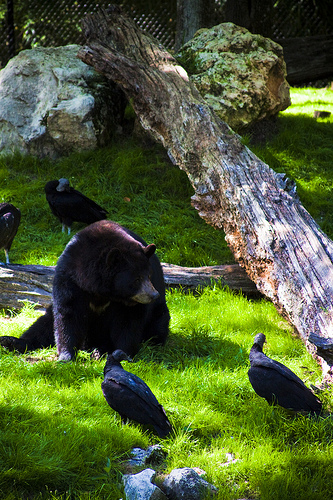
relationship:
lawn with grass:
[4, 369, 98, 462] [19, 386, 48, 416]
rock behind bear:
[172, 23, 291, 134] [0, 219, 173, 363]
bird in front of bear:
[100, 349, 177, 443] [52, 219, 172, 364]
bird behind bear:
[41, 178, 110, 236] [50, 208, 185, 344]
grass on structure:
[0, 84, 332, 497] [0, 261, 54, 315]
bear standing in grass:
[52, 219, 172, 364] [6, 297, 325, 492]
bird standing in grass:
[100, 349, 177, 443] [6, 297, 325, 492]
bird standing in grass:
[247, 333, 323, 420] [6, 297, 325, 492]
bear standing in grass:
[0, 219, 173, 363] [0, 84, 332, 497]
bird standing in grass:
[41, 178, 110, 236] [0, 84, 332, 497]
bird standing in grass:
[100, 349, 177, 443] [0, 84, 332, 497]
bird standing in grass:
[247, 333, 323, 420] [0, 84, 332, 497]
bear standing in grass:
[52, 219, 172, 364] [0, 84, 332, 497]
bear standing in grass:
[0, 219, 173, 363] [176, 290, 273, 327]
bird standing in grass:
[100, 349, 177, 443] [176, 290, 273, 327]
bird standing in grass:
[247, 333, 323, 420] [176, 290, 273, 327]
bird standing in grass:
[247, 333, 325, 412] [0, 84, 332, 497]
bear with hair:
[52, 219, 172, 364] [52, 219, 170, 366]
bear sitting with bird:
[52, 219, 172, 364] [247, 333, 329, 423]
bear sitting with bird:
[52, 219, 172, 364] [97, 347, 175, 442]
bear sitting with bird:
[52, 219, 172, 364] [41, 172, 109, 233]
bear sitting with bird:
[52, 219, 172, 364] [2, 201, 18, 260]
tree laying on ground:
[0, 10, 332, 387] [1, 88, 329, 493]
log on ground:
[74, 8, 331, 388] [1, 88, 329, 493]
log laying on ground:
[74, 8, 331, 388] [1, 88, 329, 493]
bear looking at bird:
[52, 219, 172, 364] [246, 330, 323, 416]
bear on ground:
[52, 219, 172, 364] [7, 314, 191, 368]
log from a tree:
[74, 4, 333, 387] [139, 71, 322, 373]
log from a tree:
[74, 4, 333, 387] [71, 10, 331, 373]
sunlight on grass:
[174, 402, 233, 463] [156, 375, 236, 467]